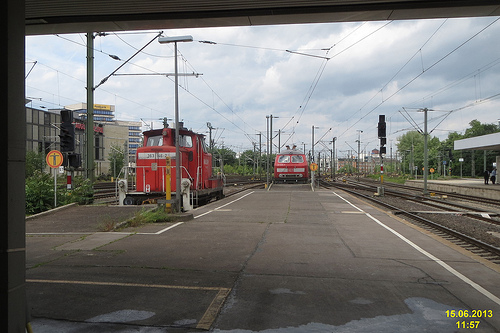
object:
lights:
[58, 109, 76, 151]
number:
[147, 153, 167, 158]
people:
[483, 169, 491, 185]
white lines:
[332, 191, 500, 306]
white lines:
[155, 190, 256, 234]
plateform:
[228, 180, 332, 331]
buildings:
[24, 97, 149, 204]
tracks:
[322, 170, 500, 255]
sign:
[46, 150, 63, 168]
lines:
[25, 20, 497, 145]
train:
[122, 128, 227, 205]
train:
[273, 145, 309, 184]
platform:
[404, 176, 498, 201]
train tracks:
[95, 182, 131, 199]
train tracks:
[226, 175, 266, 182]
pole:
[64, 152, 72, 190]